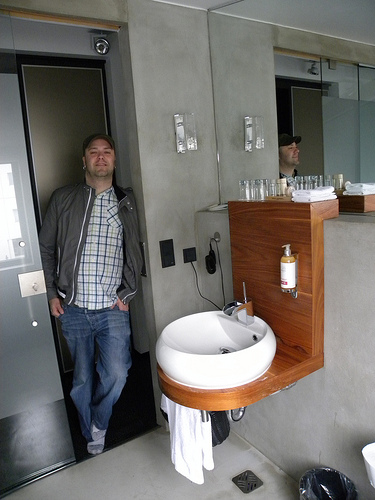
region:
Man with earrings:
[72, 131, 133, 185]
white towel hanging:
[145, 384, 229, 487]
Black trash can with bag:
[283, 455, 364, 498]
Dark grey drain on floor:
[223, 466, 271, 493]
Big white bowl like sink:
[135, 285, 297, 410]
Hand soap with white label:
[267, 237, 323, 317]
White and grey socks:
[70, 414, 134, 480]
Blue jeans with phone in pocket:
[25, 285, 164, 439]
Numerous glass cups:
[228, 175, 343, 210]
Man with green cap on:
[61, 118, 137, 195]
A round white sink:
[153, 300, 276, 393]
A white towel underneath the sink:
[157, 394, 214, 482]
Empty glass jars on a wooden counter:
[241, 176, 281, 200]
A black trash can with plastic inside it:
[299, 465, 360, 498]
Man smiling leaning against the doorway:
[36, 131, 144, 456]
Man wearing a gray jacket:
[39, 183, 140, 303]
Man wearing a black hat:
[79, 130, 120, 178]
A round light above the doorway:
[88, 26, 116, 55]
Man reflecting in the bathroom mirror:
[206, 0, 373, 211]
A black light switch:
[156, 239, 179, 271]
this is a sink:
[153, 317, 312, 442]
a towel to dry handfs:
[169, 405, 225, 463]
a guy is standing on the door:
[83, 159, 177, 468]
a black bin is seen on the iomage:
[306, 464, 374, 491]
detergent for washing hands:
[263, 252, 303, 290]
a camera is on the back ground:
[98, 31, 110, 59]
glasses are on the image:
[227, 174, 335, 219]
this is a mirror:
[276, 51, 369, 143]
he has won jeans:
[54, 309, 149, 399]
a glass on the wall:
[173, 102, 201, 160]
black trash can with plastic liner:
[298, 446, 372, 497]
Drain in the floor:
[233, 458, 270, 498]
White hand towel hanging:
[140, 375, 219, 488]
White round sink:
[153, 284, 304, 396]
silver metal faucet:
[213, 272, 258, 327]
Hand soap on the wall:
[266, 234, 306, 305]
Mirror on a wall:
[189, 61, 371, 237]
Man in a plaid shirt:
[43, 142, 159, 369]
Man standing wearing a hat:
[37, 102, 151, 436]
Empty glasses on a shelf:
[219, 170, 347, 214]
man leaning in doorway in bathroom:
[13, 92, 163, 467]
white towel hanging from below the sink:
[152, 384, 221, 484]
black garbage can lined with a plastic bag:
[285, 455, 360, 495]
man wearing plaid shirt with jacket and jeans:
[34, 132, 139, 462]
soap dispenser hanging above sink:
[270, 230, 304, 309]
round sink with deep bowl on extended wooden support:
[145, 282, 276, 398]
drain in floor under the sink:
[217, 457, 266, 492]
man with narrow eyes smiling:
[72, 109, 126, 184]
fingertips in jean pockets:
[46, 289, 140, 327]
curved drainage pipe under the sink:
[210, 400, 261, 436]